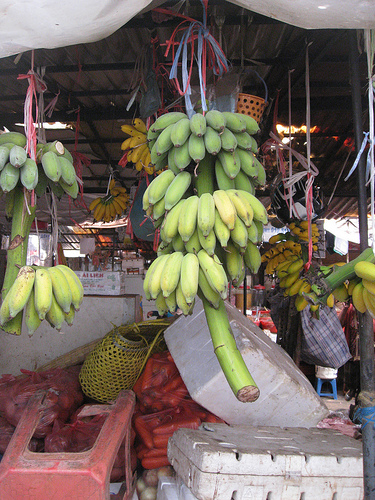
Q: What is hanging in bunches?
A: Bananas.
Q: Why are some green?
A: They are not ripe.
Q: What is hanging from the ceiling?
A: Bananas.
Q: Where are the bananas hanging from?
A: The ceiling.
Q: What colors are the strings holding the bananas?
A: Red, white,and blue.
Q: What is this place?
A: Market.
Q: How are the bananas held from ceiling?
A: String.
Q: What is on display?
A: Bananas.